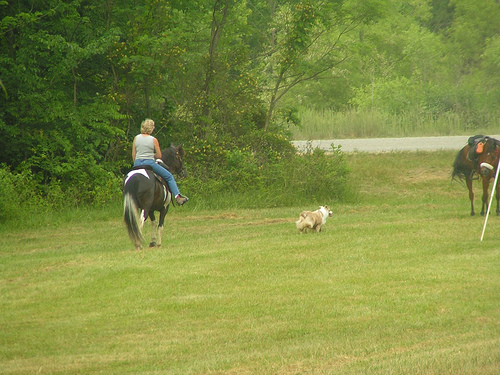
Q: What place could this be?
A: It is a field.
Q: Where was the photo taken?
A: It was taken at the field.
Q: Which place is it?
A: It is a field.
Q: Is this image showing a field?
A: Yes, it is showing a field.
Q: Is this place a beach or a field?
A: It is a field.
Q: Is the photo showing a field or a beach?
A: It is showing a field.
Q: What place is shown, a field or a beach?
A: It is a field.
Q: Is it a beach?
A: No, it is a field.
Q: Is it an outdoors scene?
A: Yes, it is outdoors.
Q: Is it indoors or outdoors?
A: It is outdoors.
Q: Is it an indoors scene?
A: No, it is outdoors.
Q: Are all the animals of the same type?
A: No, there are both horses and dogs.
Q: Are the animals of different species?
A: Yes, they are horses and dogs.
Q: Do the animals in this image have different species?
A: Yes, they are horses and dogs.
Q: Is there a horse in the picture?
A: Yes, there is a horse.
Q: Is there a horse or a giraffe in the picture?
A: Yes, there is a horse.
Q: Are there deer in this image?
A: No, there are no deer.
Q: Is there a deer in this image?
A: No, there is no deer.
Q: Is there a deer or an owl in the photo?
A: No, there are no deer or owls.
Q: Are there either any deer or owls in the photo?
A: No, there are no deer or owls.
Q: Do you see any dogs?
A: Yes, there is a dog.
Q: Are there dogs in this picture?
A: Yes, there is a dog.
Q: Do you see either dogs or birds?
A: Yes, there is a dog.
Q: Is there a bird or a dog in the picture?
A: Yes, there is a dog.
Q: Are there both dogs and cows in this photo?
A: No, there is a dog but no cows.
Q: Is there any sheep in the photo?
A: No, there is no sheep.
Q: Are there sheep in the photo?
A: No, there are no sheep.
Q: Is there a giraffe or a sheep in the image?
A: No, there are no sheep or giraffes.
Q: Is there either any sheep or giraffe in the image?
A: No, there are no sheep or giraffes.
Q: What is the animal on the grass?
A: The animal is a dog.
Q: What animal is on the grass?
A: The animal is a dog.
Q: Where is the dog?
A: The dog is on the grass.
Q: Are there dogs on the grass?
A: Yes, there is a dog on the grass.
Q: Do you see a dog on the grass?
A: Yes, there is a dog on the grass.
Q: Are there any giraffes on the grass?
A: No, there is a dog on the grass.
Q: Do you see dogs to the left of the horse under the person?
A: No, the dog is to the right of the horse.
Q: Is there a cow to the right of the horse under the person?
A: No, there is a dog to the right of the horse.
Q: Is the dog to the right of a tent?
A: No, the dog is to the right of the horse.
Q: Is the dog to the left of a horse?
A: No, the dog is to the right of a horse.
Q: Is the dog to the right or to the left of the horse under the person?
A: The dog is to the right of the horse.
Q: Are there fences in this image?
A: No, there are no fences.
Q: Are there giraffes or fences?
A: No, there are no fences or giraffes.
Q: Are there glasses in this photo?
A: No, there are no glasses.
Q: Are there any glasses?
A: No, there are no glasses.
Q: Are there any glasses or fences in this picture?
A: No, there are no glasses or fences.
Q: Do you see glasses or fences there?
A: No, there are no glasses or fences.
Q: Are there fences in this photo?
A: No, there are no fences.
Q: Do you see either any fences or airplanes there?
A: No, there are no fences or airplanes.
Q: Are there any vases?
A: No, there are no vases.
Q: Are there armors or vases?
A: No, there are no vases or armors.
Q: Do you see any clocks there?
A: No, there are no clocks.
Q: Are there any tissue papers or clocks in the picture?
A: No, there are no clocks or tissue papers.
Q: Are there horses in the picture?
A: Yes, there is a horse.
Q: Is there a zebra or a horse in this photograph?
A: Yes, there is a horse.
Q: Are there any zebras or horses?
A: Yes, there is a horse.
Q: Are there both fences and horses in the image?
A: No, there is a horse but no fences.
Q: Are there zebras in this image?
A: No, there are no zebras.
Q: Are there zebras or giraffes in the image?
A: No, there are no zebras or giraffes.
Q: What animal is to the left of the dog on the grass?
A: The animal is a horse.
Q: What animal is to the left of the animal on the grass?
A: The animal is a horse.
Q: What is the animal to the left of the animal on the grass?
A: The animal is a horse.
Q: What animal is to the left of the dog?
A: The animal is a horse.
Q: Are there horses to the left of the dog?
A: Yes, there is a horse to the left of the dog.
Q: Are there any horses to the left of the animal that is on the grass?
A: Yes, there is a horse to the left of the dog.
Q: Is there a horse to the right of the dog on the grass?
A: No, the horse is to the left of the dog.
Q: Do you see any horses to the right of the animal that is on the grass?
A: No, the horse is to the left of the dog.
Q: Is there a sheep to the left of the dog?
A: No, there is a horse to the left of the dog.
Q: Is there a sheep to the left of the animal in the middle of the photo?
A: No, there is a horse to the left of the dog.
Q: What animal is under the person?
A: The horse is under the person.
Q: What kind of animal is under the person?
A: The animal is a horse.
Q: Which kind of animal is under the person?
A: The animal is a horse.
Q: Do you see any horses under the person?
A: Yes, there is a horse under the person.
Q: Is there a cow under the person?
A: No, there is a horse under the person.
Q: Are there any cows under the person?
A: No, there is a horse under the person.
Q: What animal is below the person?
A: The animal is a horse.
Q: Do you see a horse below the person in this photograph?
A: Yes, there is a horse below the person.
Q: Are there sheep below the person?
A: No, there is a horse below the person.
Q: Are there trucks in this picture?
A: No, there are no trucks.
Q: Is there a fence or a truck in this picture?
A: No, there are no trucks or fences.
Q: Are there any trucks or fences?
A: No, there are no trucks or fences.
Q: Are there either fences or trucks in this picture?
A: No, there are no trucks or fences.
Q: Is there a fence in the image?
A: No, there are no fences.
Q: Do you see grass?
A: Yes, there is grass.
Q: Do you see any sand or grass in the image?
A: Yes, there is grass.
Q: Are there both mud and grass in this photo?
A: No, there is grass but no mud.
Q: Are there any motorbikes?
A: No, there are no motorbikes.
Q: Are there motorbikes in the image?
A: No, there are no motorbikes.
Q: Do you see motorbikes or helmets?
A: No, there are no motorbikes or helmets.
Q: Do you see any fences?
A: No, there are no fences.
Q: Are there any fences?
A: No, there are no fences.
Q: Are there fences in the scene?
A: No, there are no fences.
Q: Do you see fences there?
A: No, there are no fences.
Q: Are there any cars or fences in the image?
A: No, there are no fences or cars.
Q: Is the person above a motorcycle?
A: No, the person is above the horse.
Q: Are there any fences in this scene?
A: No, there are no fences.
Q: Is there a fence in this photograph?
A: No, there are no fences.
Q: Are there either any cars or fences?
A: No, there are no fences or cars.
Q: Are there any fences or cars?
A: No, there are no fences or cars.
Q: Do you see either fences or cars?
A: No, there are no fences or cars.